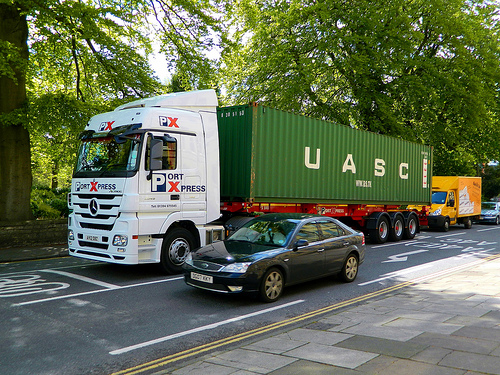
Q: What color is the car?
A: Black.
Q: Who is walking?
A: No one.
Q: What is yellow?
A: A truck.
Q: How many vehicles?
A: Four.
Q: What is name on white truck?
A: Port Xpress.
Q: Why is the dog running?
A: No dog.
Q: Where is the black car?
A: Beside truck.